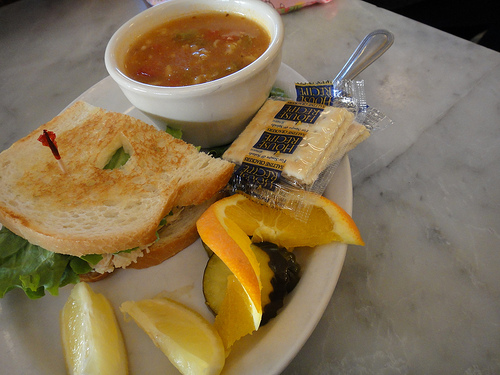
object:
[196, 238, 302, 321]
pickles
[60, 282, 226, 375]
lemon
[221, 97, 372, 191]
cracker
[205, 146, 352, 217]
wrap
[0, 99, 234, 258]
bread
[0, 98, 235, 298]
sandwich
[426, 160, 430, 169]
ground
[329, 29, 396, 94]
spoon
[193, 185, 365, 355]
orange slice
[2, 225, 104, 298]
lettuce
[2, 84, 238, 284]
sandwich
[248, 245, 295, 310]
dill pickle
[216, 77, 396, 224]
crackers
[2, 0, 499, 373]
counter top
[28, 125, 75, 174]
toothpick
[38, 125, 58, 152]
plastic curls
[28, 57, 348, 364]
plate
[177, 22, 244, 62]
soup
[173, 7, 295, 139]
white bowl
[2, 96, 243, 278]
sandwich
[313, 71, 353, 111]
ground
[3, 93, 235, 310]
food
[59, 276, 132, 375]
food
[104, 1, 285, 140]
cup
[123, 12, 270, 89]
soup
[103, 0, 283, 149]
bowl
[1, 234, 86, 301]
lettuce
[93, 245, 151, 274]
tuna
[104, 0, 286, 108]
bowl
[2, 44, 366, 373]
plate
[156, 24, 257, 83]
vegetables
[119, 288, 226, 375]
lemon